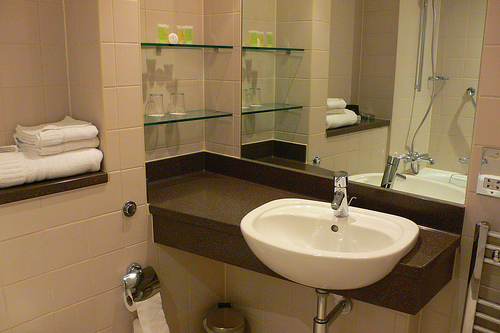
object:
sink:
[245, 205, 395, 257]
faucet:
[329, 169, 355, 220]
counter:
[146, 160, 473, 320]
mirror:
[229, 0, 498, 207]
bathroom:
[1, 0, 500, 333]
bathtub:
[418, 161, 474, 187]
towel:
[0, 136, 105, 189]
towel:
[11, 111, 102, 157]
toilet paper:
[120, 292, 175, 332]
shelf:
[142, 107, 234, 130]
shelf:
[141, 39, 234, 50]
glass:
[167, 91, 189, 117]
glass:
[144, 92, 168, 118]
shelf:
[0, 171, 111, 205]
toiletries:
[155, 21, 196, 45]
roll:
[119, 263, 168, 301]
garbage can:
[196, 308, 251, 332]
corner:
[213, 264, 234, 302]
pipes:
[315, 291, 349, 333]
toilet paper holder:
[118, 260, 166, 304]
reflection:
[378, 155, 408, 190]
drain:
[329, 223, 340, 234]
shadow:
[136, 58, 184, 104]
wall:
[0, 0, 235, 333]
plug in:
[475, 174, 500, 196]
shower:
[402, 0, 450, 177]